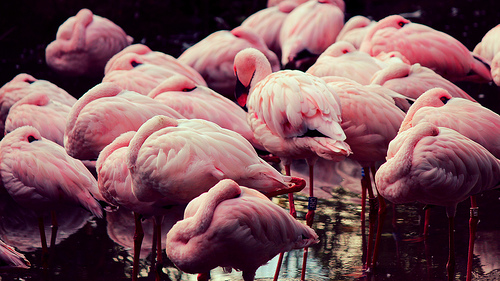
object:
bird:
[164, 178, 322, 280]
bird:
[232, 47, 355, 280]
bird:
[127, 114, 295, 279]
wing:
[249, 68, 304, 140]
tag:
[306, 196, 319, 211]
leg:
[300, 165, 314, 277]